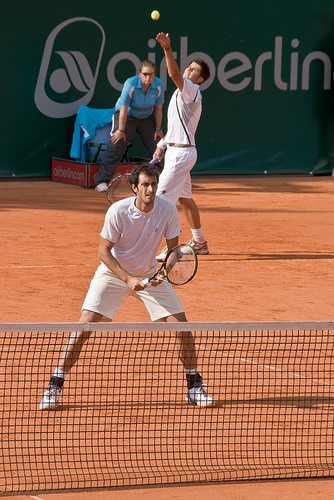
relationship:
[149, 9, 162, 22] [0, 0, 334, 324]
ball in air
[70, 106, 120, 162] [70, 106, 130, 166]
jacket on chair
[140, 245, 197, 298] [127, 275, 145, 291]
raquet in hand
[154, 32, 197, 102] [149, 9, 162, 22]
arm catching ball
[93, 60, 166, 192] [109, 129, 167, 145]
person with hands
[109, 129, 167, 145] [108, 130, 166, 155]
hands on knees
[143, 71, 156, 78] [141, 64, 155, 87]
sunglasses on face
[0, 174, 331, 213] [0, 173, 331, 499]
shadows on court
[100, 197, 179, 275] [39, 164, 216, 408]
shirt on player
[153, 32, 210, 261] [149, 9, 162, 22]
player throwing ball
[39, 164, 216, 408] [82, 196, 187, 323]
player wearing clothes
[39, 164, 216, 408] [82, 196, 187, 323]
player wears clothes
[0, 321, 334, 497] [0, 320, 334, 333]
net has border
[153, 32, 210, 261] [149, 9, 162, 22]
man throwing ball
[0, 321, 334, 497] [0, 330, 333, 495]
net has string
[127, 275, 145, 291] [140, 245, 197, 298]
hand on raquet